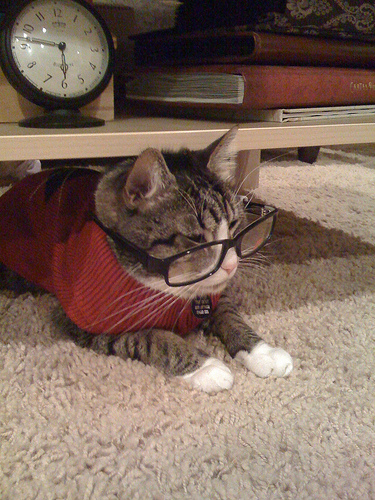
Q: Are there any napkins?
A: No, there are no napkins.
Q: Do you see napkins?
A: No, there are no napkins.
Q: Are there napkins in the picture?
A: No, there are no napkins.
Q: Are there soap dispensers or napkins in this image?
A: No, there are no napkins or soap dispensers.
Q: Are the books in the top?
A: Yes, the books are in the top of the image.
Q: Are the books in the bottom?
A: No, the books are in the top of the image.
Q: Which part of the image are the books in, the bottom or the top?
A: The books are in the top of the image.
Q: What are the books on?
A: The books are on the table.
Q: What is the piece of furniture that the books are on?
A: The piece of furniture is a table.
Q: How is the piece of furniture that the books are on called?
A: The piece of furniture is a table.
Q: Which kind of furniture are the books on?
A: The books are on the table.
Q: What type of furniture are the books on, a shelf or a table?
A: The books are on a table.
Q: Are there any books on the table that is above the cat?
A: Yes, there are books on the table.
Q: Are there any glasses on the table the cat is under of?
A: No, there are books on the table.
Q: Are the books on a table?
A: Yes, the books are on a table.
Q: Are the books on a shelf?
A: No, the books are on a table.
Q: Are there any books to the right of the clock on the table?
A: Yes, there are books to the right of the clock.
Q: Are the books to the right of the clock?
A: Yes, the books are to the right of the clock.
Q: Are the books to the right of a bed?
A: No, the books are to the right of the clock.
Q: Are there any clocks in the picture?
A: Yes, there is a clock.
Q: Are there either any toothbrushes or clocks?
A: Yes, there is a clock.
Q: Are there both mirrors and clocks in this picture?
A: No, there is a clock but no mirrors.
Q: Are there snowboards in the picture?
A: No, there are no snowboards.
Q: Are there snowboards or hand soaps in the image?
A: No, there are no snowboards or hand soaps.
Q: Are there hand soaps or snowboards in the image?
A: No, there are no snowboards or hand soaps.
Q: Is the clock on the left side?
A: Yes, the clock is on the left of the image.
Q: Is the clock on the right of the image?
A: No, the clock is on the left of the image.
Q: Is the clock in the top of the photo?
A: Yes, the clock is in the top of the image.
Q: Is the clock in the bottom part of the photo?
A: No, the clock is in the top of the image.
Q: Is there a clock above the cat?
A: Yes, there is a clock above the cat.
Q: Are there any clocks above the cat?
A: Yes, there is a clock above the cat.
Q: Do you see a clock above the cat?
A: Yes, there is a clock above the cat.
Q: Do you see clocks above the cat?
A: Yes, there is a clock above the cat.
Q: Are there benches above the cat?
A: No, there is a clock above the cat.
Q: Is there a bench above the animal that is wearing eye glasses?
A: No, there is a clock above the cat.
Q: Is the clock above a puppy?
A: No, the clock is above the cat.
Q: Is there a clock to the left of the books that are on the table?
A: Yes, there is a clock to the left of the books.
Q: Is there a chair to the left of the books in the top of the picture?
A: No, there is a clock to the left of the books.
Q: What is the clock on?
A: The clock is on the table.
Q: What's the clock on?
A: The clock is on the table.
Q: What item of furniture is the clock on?
A: The clock is on the table.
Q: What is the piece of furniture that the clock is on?
A: The piece of furniture is a table.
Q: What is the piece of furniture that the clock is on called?
A: The piece of furniture is a table.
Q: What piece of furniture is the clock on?
A: The clock is on the table.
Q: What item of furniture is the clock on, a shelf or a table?
A: The clock is on a table.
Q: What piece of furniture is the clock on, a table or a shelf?
A: The clock is on a table.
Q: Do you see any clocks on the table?
A: Yes, there is a clock on the table.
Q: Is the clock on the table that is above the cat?
A: Yes, the clock is on the table.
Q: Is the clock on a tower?
A: No, the clock is on the table.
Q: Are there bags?
A: No, there are no bags.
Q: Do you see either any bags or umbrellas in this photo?
A: No, there are no bags or umbrellas.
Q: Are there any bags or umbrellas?
A: No, there are no bags or umbrellas.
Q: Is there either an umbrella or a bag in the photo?
A: No, there are no bags or umbrellas.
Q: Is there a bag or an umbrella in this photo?
A: No, there are no bags or umbrellas.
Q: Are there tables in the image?
A: Yes, there is a table.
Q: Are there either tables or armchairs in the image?
A: Yes, there is a table.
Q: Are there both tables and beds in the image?
A: No, there is a table but no beds.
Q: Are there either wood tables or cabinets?
A: Yes, there is a wood table.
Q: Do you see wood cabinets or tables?
A: Yes, there is a wood table.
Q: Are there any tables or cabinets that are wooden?
A: Yes, the table is wooden.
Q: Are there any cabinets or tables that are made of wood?
A: Yes, the table is made of wood.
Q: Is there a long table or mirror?
A: Yes, there is a long table.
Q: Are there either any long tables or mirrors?
A: Yes, there is a long table.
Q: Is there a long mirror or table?
A: Yes, there is a long table.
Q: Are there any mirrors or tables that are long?
A: Yes, the table is long.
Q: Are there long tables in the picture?
A: Yes, there is a long table.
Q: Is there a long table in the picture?
A: Yes, there is a long table.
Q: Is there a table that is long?
A: Yes, there is a table that is long.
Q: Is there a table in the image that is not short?
A: Yes, there is a long table.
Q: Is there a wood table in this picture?
A: Yes, there is a wood table.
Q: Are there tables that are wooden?
A: Yes, there is a table that is wooden.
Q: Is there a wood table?
A: Yes, there is a table that is made of wood.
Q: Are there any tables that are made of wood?
A: Yes, there is a table that is made of wood.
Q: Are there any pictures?
A: No, there are no pictures.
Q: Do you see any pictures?
A: No, there are no pictures.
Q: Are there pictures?
A: No, there are no pictures.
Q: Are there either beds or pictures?
A: No, there are no pictures or beds.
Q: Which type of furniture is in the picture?
A: The furniture is a table.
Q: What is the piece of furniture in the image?
A: The piece of furniture is a table.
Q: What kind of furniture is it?
A: The piece of furniture is a table.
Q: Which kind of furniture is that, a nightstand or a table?
A: That is a table.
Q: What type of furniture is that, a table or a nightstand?
A: That is a table.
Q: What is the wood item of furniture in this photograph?
A: The piece of furniture is a table.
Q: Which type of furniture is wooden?
A: The furniture is a table.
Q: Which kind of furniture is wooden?
A: The furniture is a table.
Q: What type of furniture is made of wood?
A: The furniture is a table.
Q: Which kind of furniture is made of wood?
A: The furniture is a table.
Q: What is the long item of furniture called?
A: The piece of furniture is a table.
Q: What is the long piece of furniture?
A: The piece of furniture is a table.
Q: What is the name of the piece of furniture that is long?
A: The piece of furniture is a table.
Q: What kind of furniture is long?
A: The furniture is a table.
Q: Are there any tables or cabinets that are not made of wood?
A: No, there is a table but it is made of wood.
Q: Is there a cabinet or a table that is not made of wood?
A: No, there is a table but it is made of wood.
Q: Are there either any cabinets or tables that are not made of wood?
A: No, there is a table but it is made of wood.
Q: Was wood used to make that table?
A: Yes, the table is made of wood.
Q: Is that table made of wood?
A: Yes, the table is made of wood.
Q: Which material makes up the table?
A: The table is made of wood.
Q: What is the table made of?
A: The table is made of wood.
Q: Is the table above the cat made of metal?
A: No, the table is made of wood.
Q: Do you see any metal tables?
A: No, there is a table but it is made of wood.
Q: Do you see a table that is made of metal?
A: No, there is a table but it is made of wood.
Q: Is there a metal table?
A: No, there is a table but it is made of wood.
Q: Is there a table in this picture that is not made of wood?
A: No, there is a table but it is made of wood.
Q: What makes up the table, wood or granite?
A: The table is made of wood.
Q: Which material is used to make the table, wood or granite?
A: The table is made of wood.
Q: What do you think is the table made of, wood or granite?
A: The table is made of wood.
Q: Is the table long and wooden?
A: Yes, the table is long and wooden.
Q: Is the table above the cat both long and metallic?
A: No, the table is long but wooden.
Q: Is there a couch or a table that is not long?
A: No, there is a table but it is long.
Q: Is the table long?
A: Yes, the table is long.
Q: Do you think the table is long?
A: Yes, the table is long.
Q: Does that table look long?
A: Yes, the table is long.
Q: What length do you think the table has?
A: The table has long length.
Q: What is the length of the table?
A: The table is long.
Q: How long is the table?
A: The table is long.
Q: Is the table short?
A: No, the table is long.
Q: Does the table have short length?
A: No, the table is long.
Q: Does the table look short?
A: No, the table is long.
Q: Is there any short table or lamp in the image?
A: No, there is a table but it is long.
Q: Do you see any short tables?
A: No, there is a table but it is long.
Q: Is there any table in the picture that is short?
A: No, there is a table but it is long.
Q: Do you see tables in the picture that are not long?
A: No, there is a table but it is long.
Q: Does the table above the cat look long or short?
A: The table is long.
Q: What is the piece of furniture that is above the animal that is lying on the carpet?
A: The piece of furniture is a table.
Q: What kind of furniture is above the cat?
A: The piece of furniture is a table.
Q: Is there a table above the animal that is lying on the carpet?
A: Yes, there is a table above the cat.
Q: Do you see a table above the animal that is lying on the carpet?
A: Yes, there is a table above the cat.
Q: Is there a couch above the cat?
A: No, there is a table above the cat.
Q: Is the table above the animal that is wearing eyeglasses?
A: Yes, the table is above the cat.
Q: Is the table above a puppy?
A: No, the table is above the cat.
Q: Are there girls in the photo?
A: No, there are no girls.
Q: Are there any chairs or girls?
A: No, there are no girls or chairs.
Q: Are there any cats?
A: Yes, there is a cat.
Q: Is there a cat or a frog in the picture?
A: Yes, there is a cat.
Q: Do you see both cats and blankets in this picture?
A: No, there is a cat but no blankets.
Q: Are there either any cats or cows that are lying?
A: Yes, the cat is lying.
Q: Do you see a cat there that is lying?
A: Yes, there is a cat that is lying.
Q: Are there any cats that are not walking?
A: Yes, there is a cat that is lying.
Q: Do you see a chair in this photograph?
A: No, there are no chairs.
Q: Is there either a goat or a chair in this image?
A: No, there are no chairs or goats.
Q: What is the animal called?
A: The animal is a cat.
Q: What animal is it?
A: The animal is a cat.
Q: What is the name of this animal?
A: This is a cat.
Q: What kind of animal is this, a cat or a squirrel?
A: This is a cat.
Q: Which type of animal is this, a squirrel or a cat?
A: This is a cat.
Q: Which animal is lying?
A: The animal is a cat.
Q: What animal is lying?
A: The animal is a cat.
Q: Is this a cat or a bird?
A: This is a cat.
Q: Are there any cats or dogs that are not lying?
A: No, there is a cat but it is lying.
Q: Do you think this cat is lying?
A: Yes, the cat is lying.